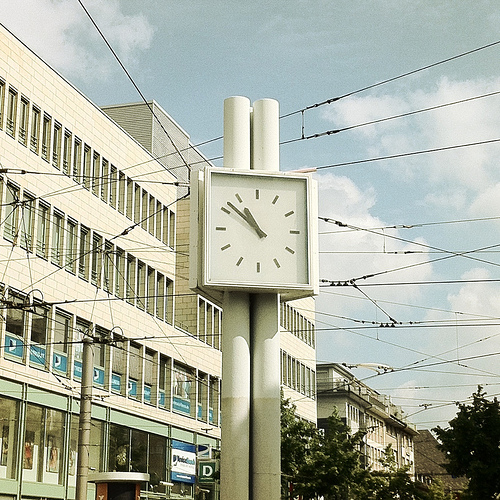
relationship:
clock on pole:
[189, 166, 328, 316] [202, 167, 330, 307]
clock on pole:
[200, 166, 313, 290] [197, 96, 320, 493]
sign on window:
[166, 447, 201, 477] [142, 430, 173, 495]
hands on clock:
[226, 203, 270, 243] [200, 174, 311, 289]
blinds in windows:
[40, 136, 78, 291] [23, 87, 110, 311]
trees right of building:
[282, 383, 497, 499] [0, 27, 317, 497]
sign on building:
[164, 437, 204, 486] [0, 27, 317, 497]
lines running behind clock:
[123, 144, 492, 386] [200, 166, 325, 295]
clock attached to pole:
[200, 166, 313, 290] [214, 289, 306, 499]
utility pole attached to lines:
[70, 335, 100, 499] [0, 60, 500, 428]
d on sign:
[190, 460, 217, 479] [188, 453, 217, 488]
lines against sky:
[0, 60, 500, 428] [1, 1, 497, 422]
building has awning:
[2, 20, 362, 497] [79, 462, 160, 482]